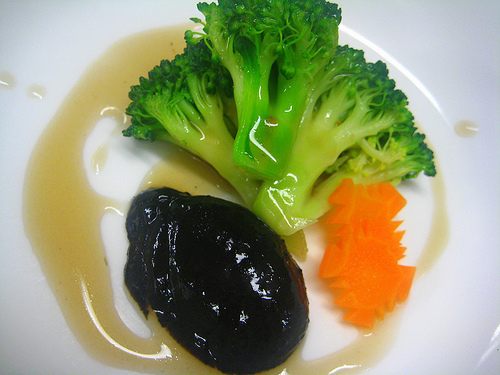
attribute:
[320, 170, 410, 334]
vegetable — decoratively cut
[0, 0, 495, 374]
plate — white 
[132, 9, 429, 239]
brocolli — cooked, green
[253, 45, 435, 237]
broccolli — green, cooked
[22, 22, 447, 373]
sauce — brown 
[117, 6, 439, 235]
brocolli — green, cooked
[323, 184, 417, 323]
carrot — carved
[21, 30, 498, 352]
plate — white, ceramic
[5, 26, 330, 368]
sauce — yellowy brown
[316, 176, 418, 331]
carrot — orange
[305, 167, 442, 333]
carrot — orange 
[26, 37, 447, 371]
liquid — brown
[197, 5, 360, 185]
twin floret — bright kelly green